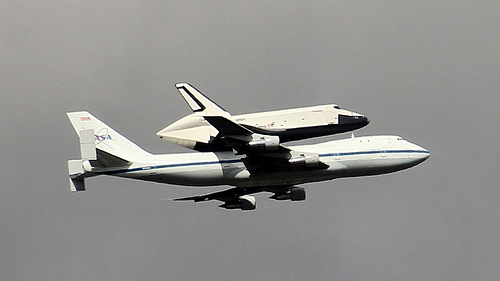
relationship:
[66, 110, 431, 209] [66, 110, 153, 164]
plane has a tail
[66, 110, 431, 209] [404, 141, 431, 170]
plane has a nose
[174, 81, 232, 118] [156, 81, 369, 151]
tail on th space shuttle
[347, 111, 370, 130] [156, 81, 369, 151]
nose on space shuttle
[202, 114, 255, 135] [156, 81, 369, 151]
wing on space shuttle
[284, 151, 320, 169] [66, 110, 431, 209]
engine on plane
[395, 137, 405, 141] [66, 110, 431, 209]
windshield on plane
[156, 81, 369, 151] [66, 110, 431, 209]
space shuttle riding on plane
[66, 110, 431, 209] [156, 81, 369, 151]
plane under space shuttle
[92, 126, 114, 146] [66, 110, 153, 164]
logo on tail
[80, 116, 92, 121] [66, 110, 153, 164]
flag on tail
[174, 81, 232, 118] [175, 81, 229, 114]
tail has some lines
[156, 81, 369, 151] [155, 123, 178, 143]
space shuttle has a point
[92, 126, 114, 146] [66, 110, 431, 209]
logo on plane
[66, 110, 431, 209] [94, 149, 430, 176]
plane has a stripe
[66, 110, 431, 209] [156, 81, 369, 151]
plane carrying space shuttle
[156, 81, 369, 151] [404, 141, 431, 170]
space shuttle has a black nose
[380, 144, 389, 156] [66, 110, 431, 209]
door on plane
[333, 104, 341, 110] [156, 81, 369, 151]
window on space shuttle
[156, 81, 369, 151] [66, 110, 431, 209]
space shuttle on plane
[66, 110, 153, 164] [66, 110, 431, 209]
tail on large plane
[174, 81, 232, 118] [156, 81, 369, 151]
tail on space shuttle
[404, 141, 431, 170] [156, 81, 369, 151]
nose on space shuttle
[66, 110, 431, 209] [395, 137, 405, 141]
plane has a windshield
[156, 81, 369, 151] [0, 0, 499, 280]
space shuttle in sky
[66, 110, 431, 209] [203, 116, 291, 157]
plane has a wing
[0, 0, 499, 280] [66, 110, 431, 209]
sky behind plane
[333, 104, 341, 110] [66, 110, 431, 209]
window on plane